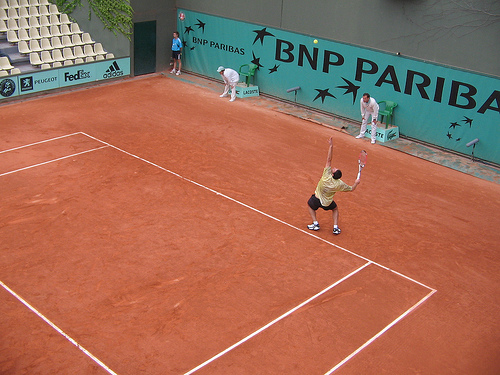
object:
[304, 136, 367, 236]
man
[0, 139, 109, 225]
court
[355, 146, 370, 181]
racket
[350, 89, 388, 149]
people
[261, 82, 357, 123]
side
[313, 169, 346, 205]
shirt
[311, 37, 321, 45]
ball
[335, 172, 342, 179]
hair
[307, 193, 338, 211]
shorts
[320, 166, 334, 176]
sleeves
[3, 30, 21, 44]
seats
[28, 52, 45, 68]
chairs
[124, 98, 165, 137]
ground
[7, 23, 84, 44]
rows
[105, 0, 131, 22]
ivy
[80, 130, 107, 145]
lines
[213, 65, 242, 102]
man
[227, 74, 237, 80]
white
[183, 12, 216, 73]
wall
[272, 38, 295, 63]
letters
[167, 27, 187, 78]
person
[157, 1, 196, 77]
corner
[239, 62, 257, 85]
chair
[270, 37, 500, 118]
sign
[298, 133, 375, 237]
player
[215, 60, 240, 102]
umpires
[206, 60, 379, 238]
match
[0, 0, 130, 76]
stands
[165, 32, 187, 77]
boy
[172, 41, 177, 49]
blue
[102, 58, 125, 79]
addidas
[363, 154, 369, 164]
red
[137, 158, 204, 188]
line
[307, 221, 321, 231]
shoe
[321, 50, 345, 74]
letter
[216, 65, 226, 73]
cap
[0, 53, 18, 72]
seat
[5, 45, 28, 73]
stairs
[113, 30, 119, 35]
leaves